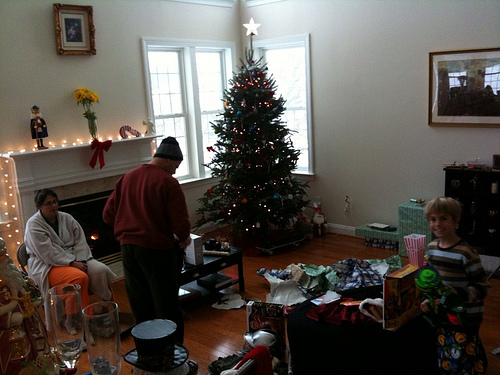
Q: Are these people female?
A: No, they are both male and female.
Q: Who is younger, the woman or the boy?
A: The boy is younger than the woman.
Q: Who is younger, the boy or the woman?
A: The boy is younger than the woman.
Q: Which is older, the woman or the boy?
A: The woman is older than the boy.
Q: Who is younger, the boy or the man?
A: The boy is younger than the man.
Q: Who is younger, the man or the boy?
A: The boy is younger than the man.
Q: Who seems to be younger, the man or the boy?
A: The boy is younger than the man.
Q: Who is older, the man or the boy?
A: The man is older than the boy.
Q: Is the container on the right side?
A: Yes, the container is on the right of the image.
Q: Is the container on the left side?
A: No, the container is on the right of the image.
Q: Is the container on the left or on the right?
A: The container is on the right of the image.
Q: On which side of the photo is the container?
A: The container is on the right of the image.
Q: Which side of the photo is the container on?
A: The container is on the right of the image.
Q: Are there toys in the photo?
A: Yes, there is a toy.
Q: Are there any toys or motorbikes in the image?
A: Yes, there is a toy.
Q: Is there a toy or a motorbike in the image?
A: Yes, there is a toy.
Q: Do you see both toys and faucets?
A: No, there is a toy but no faucets.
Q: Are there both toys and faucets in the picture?
A: No, there is a toy but no faucets.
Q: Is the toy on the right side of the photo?
A: Yes, the toy is on the right of the image.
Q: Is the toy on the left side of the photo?
A: No, the toy is on the right of the image.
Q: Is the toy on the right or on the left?
A: The toy is on the right of the image.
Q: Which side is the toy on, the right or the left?
A: The toy is on the right of the image.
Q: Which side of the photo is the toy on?
A: The toy is on the right of the image.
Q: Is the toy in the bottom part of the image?
A: Yes, the toy is in the bottom of the image.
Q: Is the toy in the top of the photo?
A: No, the toy is in the bottom of the image.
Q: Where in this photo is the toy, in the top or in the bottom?
A: The toy is in the bottom of the image.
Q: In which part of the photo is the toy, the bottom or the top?
A: The toy is in the bottom of the image.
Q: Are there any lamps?
A: No, there are no lamps.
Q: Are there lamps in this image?
A: No, there are no lamps.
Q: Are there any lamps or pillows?
A: No, there are no lamps or pillows.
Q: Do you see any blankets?
A: No, there are no blankets.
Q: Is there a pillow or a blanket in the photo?
A: No, there are no blankets or pillows.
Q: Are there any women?
A: Yes, there is a woman.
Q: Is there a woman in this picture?
A: Yes, there is a woman.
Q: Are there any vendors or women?
A: Yes, there is a woman.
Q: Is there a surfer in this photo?
A: No, there are no surfers.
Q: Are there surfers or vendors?
A: No, there are no surfers or vendors.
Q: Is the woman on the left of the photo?
A: Yes, the woman is on the left of the image.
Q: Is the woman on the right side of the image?
A: No, the woman is on the left of the image.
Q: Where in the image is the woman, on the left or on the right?
A: The woman is on the left of the image.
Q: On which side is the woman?
A: The woman is on the left of the image.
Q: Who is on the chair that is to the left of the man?
A: The woman is on the chair.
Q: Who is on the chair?
A: The woman is on the chair.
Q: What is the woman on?
A: The woman is on the chair.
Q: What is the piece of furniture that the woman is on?
A: The piece of furniture is a chair.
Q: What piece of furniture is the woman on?
A: The woman is on the chair.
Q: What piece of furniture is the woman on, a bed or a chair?
A: The woman is on a chair.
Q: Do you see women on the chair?
A: Yes, there is a woman on the chair.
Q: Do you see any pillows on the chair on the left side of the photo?
A: No, there is a woman on the chair.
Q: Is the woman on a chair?
A: Yes, the woman is on a chair.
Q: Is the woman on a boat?
A: No, the woman is on a chair.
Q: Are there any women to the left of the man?
A: Yes, there is a woman to the left of the man.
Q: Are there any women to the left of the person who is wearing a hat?
A: Yes, there is a woman to the left of the man.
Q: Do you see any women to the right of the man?
A: No, the woman is to the left of the man.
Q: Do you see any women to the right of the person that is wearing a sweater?
A: No, the woman is to the left of the man.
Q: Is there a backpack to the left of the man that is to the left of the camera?
A: No, there is a woman to the left of the man.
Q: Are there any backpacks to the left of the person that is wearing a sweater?
A: No, there is a woman to the left of the man.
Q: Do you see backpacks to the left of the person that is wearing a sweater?
A: No, there is a woman to the left of the man.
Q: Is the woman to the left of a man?
A: Yes, the woman is to the left of a man.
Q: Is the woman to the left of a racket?
A: No, the woman is to the left of a man.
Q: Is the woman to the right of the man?
A: No, the woman is to the left of the man.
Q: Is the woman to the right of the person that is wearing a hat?
A: No, the woman is to the left of the man.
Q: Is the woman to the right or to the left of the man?
A: The woman is to the left of the man.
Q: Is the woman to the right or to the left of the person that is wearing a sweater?
A: The woman is to the left of the man.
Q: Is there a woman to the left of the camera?
A: Yes, there is a woman to the left of the camera.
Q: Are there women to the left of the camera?
A: Yes, there is a woman to the left of the camera.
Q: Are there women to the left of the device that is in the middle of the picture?
A: Yes, there is a woman to the left of the camera.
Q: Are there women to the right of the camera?
A: No, the woman is to the left of the camera.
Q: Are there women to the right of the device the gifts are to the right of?
A: No, the woman is to the left of the camera.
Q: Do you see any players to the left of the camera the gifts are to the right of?
A: No, there is a woman to the left of the camera.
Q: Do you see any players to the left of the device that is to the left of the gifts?
A: No, there is a woman to the left of the camera.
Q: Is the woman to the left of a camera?
A: Yes, the woman is to the left of a camera.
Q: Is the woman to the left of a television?
A: No, the woman is to the left of a camera.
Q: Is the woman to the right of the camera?
A: No, the woman is to the left of the camera.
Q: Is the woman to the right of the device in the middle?
A: No, the woman is to the left of the camera.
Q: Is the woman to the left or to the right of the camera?
A: The woman is to the left of the camera.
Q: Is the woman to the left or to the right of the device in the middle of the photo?
A: The woman is to the left of the camera.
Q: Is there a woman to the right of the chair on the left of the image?
A: Yes, there is a woman to the right of the chair.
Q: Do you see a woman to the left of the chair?
A: No, the woman is to the right of the chair.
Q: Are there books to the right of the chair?
A: No, there is a woman to the right of the chair.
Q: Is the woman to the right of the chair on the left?
A: Yes, the woman is to the right of the chair.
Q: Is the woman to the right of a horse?
A: No, the woman is to the right of the chair.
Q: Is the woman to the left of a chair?
A: No, the woman is to the right of a chair.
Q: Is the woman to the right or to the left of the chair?
A: The woman is to the right of the chair.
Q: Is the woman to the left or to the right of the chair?
A: The woman is to the right of the chair.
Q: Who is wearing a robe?
A: The woman is wearing a robe.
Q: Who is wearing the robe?
A: The woman is wearing a robe.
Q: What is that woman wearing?
A: The woman is wearing a robe.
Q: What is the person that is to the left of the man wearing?
A: The woman is wearing a robe.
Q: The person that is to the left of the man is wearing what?
A: The woman is wearing a robe.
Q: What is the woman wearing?
A: The woman is wearing a robe.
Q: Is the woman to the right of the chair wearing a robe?
A: Yes, the woman is wearing a robe.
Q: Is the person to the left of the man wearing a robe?
A: Yes, the woman is wearing a robe.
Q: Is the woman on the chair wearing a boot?
A: No, the woman is wearing a robe.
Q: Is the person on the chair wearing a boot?
A: No, the woman is wearing a robe.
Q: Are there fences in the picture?
A: No, there are no fences.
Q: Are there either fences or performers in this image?
A: No, there are no fences or performers.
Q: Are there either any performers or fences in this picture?
A: No, there are no fences or performers.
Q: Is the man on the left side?
A: Yes, the man is on the left of the image.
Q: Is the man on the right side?
A: No, the man is on the left of the image.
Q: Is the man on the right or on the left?
A: The man is on the left of the image.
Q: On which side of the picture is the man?
A: The man is on the left of the image.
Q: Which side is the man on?
A: The man is on the left of the image.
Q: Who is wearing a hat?
A: The man is wearing a hat.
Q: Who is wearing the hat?
A: The man is wearing a hat.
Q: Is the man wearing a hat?
A: Yes, the man is wearing a hat.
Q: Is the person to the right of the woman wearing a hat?
A: Yes, the man is wearing a hat.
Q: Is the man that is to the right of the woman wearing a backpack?
A: No, the man is wearing a hat.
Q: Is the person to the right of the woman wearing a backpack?
A: No, the man is wearing a hat.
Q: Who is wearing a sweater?
A: The man is wearing a sweater.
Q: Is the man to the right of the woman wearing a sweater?
A: Yes, the man is wearing a sweater.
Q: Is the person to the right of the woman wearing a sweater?
A: Yes, the man is wearing a sweater.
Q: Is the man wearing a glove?
A: No, the man is wearing a sweater.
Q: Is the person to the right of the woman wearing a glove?
A: No, the man is wearing a sweater.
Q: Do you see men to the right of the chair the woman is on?
A: Yes, there is a man to the right of the chair.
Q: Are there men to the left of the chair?
A: No, the man is to the right of the chair.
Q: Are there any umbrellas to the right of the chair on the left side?
A: No, there is a man to the right of the chair.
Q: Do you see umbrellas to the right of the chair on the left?
A: No, there is a man to the right of the chair.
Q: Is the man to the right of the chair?
A: Yes, the man is to the right of the chair.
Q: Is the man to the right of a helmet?
A: No, the man is to the right of the chair.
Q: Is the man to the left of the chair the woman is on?
A: No, the man is to the right of the chair.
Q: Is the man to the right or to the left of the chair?
A: The man is to the right of the chair.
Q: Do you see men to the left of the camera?
A: Yes, there is a man to the left of the camera.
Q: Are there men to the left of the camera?
A: Yes, there is a man to the left of the camera.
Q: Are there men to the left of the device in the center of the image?
A: Yes, there is a man to the left of the camera.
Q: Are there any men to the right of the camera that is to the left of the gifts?
A: No, the man is to the left of the camera.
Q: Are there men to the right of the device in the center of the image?
A: No, the man is to the left of the camera.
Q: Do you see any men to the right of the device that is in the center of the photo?
A: No, the man is to the left of the camera.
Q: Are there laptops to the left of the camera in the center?
A: No, there is a man to the left of the camera.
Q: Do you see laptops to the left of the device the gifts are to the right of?
A: No, there is a man to the left of the camera.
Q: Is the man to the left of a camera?
A: Yes, the man is to the left of a camera.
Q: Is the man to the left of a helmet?
A: No, the man is to the left of a camera.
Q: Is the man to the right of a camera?
A: No, the man is to the left of a camera.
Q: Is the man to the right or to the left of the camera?
A: The man is to the left of the camera.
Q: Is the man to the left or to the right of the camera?
A: The man is to the left of the camera.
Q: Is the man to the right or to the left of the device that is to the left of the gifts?
A: The man is to the left of the camera.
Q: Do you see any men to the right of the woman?
A: Yes, there is a man to the right of the woman.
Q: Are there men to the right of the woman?
A: Yes, there is a man to the right of the woman.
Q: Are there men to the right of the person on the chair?
A: Yes, there is a man to the right of the woman.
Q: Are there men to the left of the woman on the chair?
A: No, the man is to the right of the woman.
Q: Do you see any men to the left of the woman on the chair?
A: No, the man is to the right of the woman.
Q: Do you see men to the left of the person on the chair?
A: No, the man is to the right of the woman.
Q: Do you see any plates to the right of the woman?
A: No, there is a man to the right of the woman.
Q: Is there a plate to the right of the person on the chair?
A: No, there is a man to the right of the woman.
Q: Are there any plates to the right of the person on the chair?
A: No, there is a man to the right of the woman.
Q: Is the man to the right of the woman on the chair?
A: Yes, the man is to the right of the woman.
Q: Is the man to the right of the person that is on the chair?
A: Yes, the man is to the right of the woman.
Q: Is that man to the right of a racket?
A: No, the man is to the right of the woman.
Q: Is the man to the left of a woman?
A: No, the man is to the right of a woman.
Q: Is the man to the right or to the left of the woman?
A: The man is to the right of the woman.